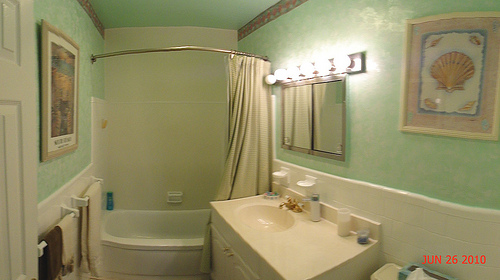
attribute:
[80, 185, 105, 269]
towel — tan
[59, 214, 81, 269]
towel — tan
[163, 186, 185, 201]
dish — soap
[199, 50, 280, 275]
curtain — shower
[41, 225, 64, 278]
bowl towel — brown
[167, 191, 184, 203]
holder — soap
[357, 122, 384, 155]
wall — green, painted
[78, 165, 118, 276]
towel — white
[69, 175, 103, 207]
rod — towel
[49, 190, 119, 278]
towels — hand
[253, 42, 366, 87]
lights — row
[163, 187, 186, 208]
soap dish — white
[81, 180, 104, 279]
towel — tan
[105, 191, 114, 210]
bottle — blue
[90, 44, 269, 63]
rod — metal, curtain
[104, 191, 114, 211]
shampoo bottle — blue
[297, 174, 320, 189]
soap dish — white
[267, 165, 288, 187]
soap dish — white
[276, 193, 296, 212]
faucet — brass, colored